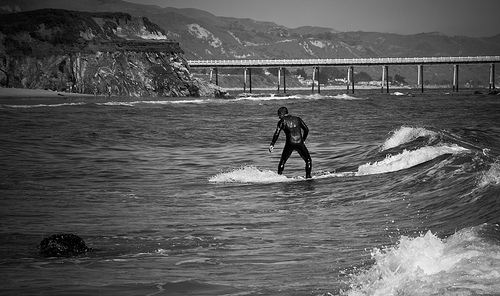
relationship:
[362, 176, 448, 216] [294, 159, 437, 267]
ripples in water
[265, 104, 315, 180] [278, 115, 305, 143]
man wears wet suit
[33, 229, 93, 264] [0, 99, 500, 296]
object in ocean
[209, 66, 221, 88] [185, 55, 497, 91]
pillar in bridge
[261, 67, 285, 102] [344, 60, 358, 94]
pillar on bridge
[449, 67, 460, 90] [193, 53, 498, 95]
pillar in bridge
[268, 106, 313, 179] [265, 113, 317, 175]
man wears wet suit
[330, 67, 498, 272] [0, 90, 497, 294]
waves of an ocean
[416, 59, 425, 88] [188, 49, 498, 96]
pillar in bridge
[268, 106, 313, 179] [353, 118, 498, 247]
man riding a wave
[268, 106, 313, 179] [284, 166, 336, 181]
man standing in surfboard